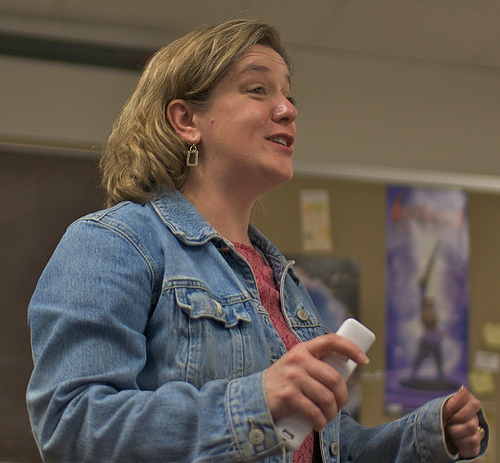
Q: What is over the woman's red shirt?
A: A denim jacket.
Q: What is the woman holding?
A: A remote control.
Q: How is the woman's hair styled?
A: To the side and curled under.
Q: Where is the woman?
A: In a room with a tan corkboard.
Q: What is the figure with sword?
A: Poster.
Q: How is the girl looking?
A: Smiling.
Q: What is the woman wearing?
A: Blue jean.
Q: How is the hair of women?
A: Blonde.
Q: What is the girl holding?
A: Remote.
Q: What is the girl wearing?
A: Ring.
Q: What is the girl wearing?
A: Red shirt.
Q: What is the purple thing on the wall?
A: A poster.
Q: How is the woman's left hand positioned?
A: In a fist.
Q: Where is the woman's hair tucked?
A: Behind her ear.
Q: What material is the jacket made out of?
A: Denim.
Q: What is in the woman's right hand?
A: A game controller.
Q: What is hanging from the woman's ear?
A: An earring.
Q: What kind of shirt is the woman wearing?
A: A rose colored t-shirt.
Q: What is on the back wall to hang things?
A: A bulletin board.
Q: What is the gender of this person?
A: Female.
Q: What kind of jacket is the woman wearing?
A: Denim jacket.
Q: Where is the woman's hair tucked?
A: Behind the ear.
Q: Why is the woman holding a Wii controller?
A: The woman is playing video games.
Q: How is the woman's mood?
A: Happy.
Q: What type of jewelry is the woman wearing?
A: Earring.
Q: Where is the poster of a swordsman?
A: To the right of the woman.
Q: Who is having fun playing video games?
A: The woman.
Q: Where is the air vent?
A: To the left of the woman's head.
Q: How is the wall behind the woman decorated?
A: With posters.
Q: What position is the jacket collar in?
A: Down.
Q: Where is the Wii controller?
A: Woman's right hand.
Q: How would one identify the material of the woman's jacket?
A: Denim.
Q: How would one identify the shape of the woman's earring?
A: Rectangular.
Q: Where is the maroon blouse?
A: Under the jacket.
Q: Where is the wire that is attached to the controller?
A: On the bottom.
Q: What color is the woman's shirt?
A: Pink.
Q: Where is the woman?
A: In the center of the photo.